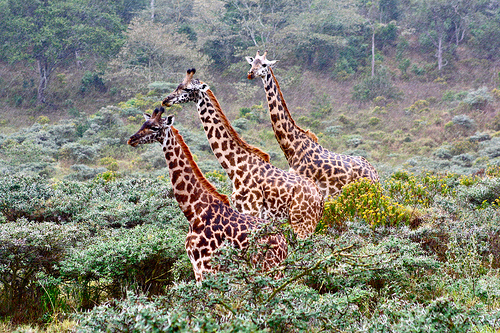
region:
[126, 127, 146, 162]
Giraffe has brown and black nose.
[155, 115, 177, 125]
Giraffe has white and black ear.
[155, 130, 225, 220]
Giraffe has long neck.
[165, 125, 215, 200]
Brown hair down giraffe's neck.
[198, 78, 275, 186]
Brown hair down giraffe's neck.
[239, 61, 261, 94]
Giraffe has brown nose.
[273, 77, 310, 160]
Giraffe has long neck.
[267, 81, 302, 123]
Brown hair down giraffe's neck.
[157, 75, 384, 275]
3 giraffes standing in field.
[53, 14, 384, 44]
Many trees in distance.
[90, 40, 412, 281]
three giraffes in the bushes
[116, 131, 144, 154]
a giraffes nose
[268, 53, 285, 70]
the ear of a giraffe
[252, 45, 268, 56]
Horns on a giraffe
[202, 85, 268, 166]
the main on a giraffe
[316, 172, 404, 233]
yellow leaves in a bush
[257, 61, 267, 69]
the eye of a giraffe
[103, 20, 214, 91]
a tree with brown leaves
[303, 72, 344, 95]
a bare spot on the hill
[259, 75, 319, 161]
the long neck of a giraffe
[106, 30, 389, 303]
three giraffe's standing in the forest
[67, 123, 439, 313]
lot of plants with giraffe's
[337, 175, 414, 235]
flowers in the plant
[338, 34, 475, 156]
dirt with lot of plants and trees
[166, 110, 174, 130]
ear of the giraffe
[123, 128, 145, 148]
mouth and nose of the giraffe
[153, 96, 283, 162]
neck of the giraffe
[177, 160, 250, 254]
brown and cream color polygon shape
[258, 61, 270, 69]
eye of the giraffe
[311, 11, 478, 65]
trees with branches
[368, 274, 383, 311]
part of a forest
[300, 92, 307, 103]
part of a wall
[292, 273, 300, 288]
part of a bush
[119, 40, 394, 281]
three giraffes facing left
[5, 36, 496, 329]
giraffes in a field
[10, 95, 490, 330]
a field covered with tall plants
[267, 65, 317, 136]
mane of giraffe is brown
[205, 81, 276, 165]
mane of giraffe is brown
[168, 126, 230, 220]
mane of giraffe is brown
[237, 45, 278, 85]
small head of giraffe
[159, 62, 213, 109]
small head of giraffe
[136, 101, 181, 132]
ears of giraffe are on side the head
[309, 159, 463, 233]
plants with yellow plants